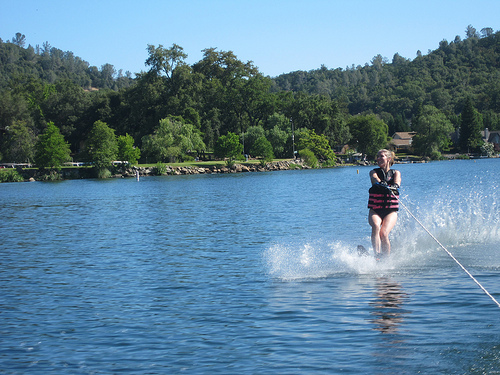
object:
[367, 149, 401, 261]
woman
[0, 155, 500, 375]
lake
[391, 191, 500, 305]
tether line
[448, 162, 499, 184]
water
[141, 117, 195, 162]
small trees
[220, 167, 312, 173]
shoreline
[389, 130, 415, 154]
house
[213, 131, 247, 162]
trees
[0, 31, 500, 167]
mountains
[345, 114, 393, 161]
trees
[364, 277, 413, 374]
reflection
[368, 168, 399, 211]
black bathing suit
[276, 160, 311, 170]
rocks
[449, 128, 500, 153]
houses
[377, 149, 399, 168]
hair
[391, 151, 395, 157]
bun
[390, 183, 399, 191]
black gloves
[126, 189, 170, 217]
ripples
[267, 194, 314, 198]
part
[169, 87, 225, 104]
part